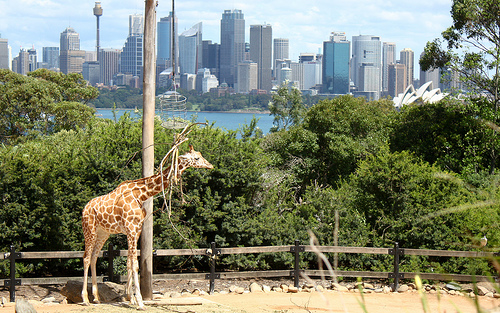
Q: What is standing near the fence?
A: A giraffe.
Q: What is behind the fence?
A: Trees.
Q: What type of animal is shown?
A: Giraffe.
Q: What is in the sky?
A: Clouds.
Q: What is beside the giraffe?
A: Fence.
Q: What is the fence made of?
A: Wood.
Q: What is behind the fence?
A: Trees.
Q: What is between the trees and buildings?
A: Water.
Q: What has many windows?
A: The buildings.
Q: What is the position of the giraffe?
A: Standing.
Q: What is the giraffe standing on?
A: Dirt.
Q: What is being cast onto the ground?
A: Shadows.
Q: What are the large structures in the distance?
A: Buildings.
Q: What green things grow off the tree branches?
A: Leaves.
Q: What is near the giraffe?
A: Fence.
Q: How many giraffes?
A: 1.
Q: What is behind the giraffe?
A: Trees.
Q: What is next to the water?
A: Buildings.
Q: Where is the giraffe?
A: In front of the trees.